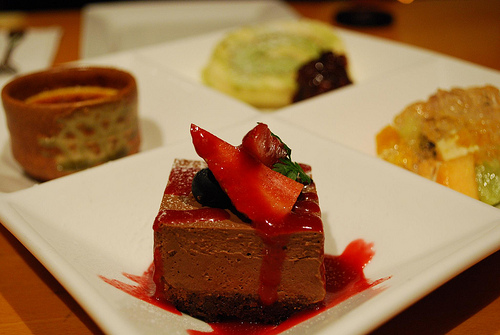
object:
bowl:
[2, 60, 141, 184]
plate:
[0, 116, 498, 334]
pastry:
[150, 157, 325, 324]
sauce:
[96, 239, 382, 334]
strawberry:
[190, 122, 306, 229]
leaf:
[269, 150, 313, 187]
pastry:
[373, 83, 500, 206]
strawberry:
[240, 122, 294, 172]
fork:
[1, 25, 27, 78]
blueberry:
[190, 167, 236, 210]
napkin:
[2, 25, 67, 77]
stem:
[271, 132, 293, 156]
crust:
[167, 285, 328, 330]